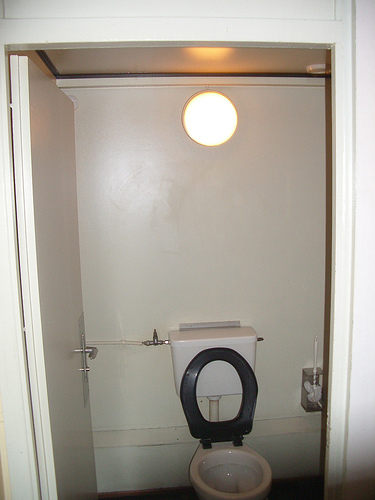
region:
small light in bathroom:
[169, 81, 248, 149]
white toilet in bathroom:
[160, 319, 274, 495]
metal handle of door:
[68, 324, 108, 394]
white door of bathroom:
[20, 78, 125, 496]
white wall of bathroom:
[86, 92, 337, 499]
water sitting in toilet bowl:
[216, 468, 246, 491]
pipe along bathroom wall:
[78, 331, 162, 355]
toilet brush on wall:
[296, 376, 326, 425]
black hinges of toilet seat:
[197, 428, 246, 449]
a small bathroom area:
[37, 259, 328, 497]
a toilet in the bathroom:
[152, 324, 289, 497]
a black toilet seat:
[168, 341, 268, 449]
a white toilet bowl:
[187, 446, 277, 493]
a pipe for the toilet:
[73, 318, 167, 379]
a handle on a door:
[59, 325, 121, 394]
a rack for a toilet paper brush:
[295, 354, 335, 419]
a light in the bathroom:
[163, 87, 271, 148]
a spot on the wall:
[168, 311, 253, 331]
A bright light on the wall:
[182, 88, 238, 146]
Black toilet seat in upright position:
[178, 347, 259, 444]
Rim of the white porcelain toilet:
[188, 444, 272, 498]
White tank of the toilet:
[167, 325, 254, 396]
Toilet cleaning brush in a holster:
[300, 337, 323, 413]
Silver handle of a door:
[84, 344, 97, 360]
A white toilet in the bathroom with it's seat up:
[170, 314, 272, 497]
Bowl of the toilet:
[194, 447, 262, 492]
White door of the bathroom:
[10, 50, 102, 497]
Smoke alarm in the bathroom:
[305, 60, 331, 77]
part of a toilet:
[256, 490, 262, 497]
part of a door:
[53, 369, 57, 377]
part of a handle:
[82, 346, 92, 359]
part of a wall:
[133, 400, 138, 415]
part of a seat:
[209, 451, 213, 459]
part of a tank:
[203, 344, 211, 371]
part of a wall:
[143, 461, 147, 474]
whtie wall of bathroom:
[82, 116, 283, 497]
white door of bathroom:
[12, 109, 89, 497]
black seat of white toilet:
[187, 359, 251, 438]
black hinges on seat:
[201, 435, 250, 450]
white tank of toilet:
[189, 340, 249, 404]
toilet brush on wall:
[302, 363, 336, 412]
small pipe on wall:
[83, 333, 169, 350]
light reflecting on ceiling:
[189, 45, 225, 66]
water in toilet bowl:
[216, 469, 243, 490]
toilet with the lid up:
[162, 307, 283, 493]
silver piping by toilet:
[140, 322, 167, 362]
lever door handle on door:
[77, 332, 104, 385]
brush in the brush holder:
[294, 346, 327, 418]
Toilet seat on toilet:
[166, 347, 280, 447]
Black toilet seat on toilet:
[174, 338, 266, 443]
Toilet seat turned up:
[159, 347, 266, 446]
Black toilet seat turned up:
[170, 351, 274, 451]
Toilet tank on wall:
[158, 325, 273, 400]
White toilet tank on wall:
[163, 325, 272, 402]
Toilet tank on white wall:
[160, 321, 267, 401]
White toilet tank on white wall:
[150, 324, 273, 403]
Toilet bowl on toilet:
[184, 440, 280, 498]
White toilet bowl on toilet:
[171, 441, 284, 494]